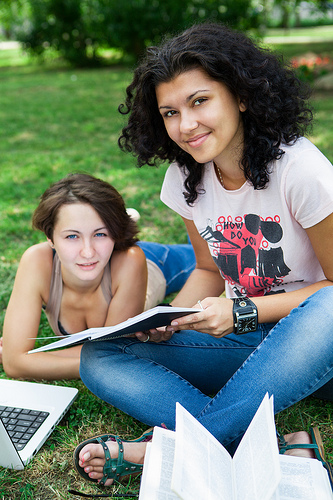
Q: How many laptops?
A: One.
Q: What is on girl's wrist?
A: Watch.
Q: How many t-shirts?
A: One.